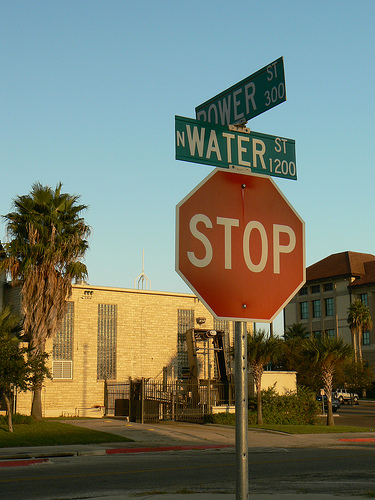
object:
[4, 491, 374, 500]
edge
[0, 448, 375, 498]
road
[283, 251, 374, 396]
house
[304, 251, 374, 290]
roof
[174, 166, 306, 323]
sign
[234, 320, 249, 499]
pole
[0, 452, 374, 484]
lines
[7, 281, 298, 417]
building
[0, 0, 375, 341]
sky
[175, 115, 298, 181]
sign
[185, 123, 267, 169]
water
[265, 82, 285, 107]
number 300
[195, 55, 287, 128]
sign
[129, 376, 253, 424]
gate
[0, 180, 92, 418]
palm tree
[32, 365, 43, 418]
trunk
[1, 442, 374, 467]
sidewalk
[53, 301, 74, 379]
window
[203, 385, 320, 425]
hedge